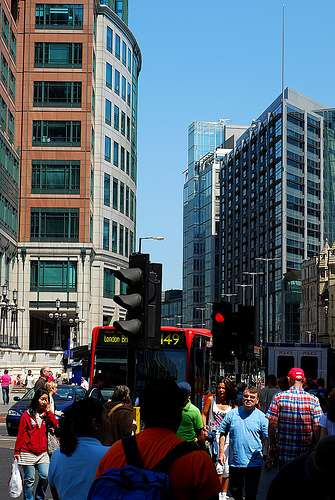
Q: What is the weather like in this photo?
A: It is clear.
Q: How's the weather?
A: It is clear.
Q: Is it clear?
A: Yes, it is clear.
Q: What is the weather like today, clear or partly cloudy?
A: It is clear.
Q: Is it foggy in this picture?
A: No, it is clear.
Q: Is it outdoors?
A: Yes, it is outdoors.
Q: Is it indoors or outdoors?
A: It is outdoors.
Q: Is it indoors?
A: No, it is outdoors.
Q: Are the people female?
A: No, they are both male and female.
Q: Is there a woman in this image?
A: Yes, there is a woman.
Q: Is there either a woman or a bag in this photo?
A: Yes, there is a woman.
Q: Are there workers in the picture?
A: No, there are no workers.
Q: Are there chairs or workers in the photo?
A: No, there are no workers or chairs.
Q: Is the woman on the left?
A: Yes, the woman is on the left of the image.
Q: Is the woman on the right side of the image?
A: No, the woman is on the left of the image.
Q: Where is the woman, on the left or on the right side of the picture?
A: The woman is on the left of the image.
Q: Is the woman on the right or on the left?
A: The woman is on the left of the image.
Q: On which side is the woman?
A: The woman is on the left of the image.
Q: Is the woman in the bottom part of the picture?
A: Yes, the woman is in the bottom of the image.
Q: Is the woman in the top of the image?
A: No, the woman is in the bottom of the image.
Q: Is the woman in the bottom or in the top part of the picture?
A: The woman is in the bottom of the image.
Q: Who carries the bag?
A: The woman carries the bag.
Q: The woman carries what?
A: The woman carries a bag.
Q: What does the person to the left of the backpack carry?
A: The woman carries a bag.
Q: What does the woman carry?
A: The woman carries a bag.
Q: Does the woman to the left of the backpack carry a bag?
A: Yes, the woman carries a bag.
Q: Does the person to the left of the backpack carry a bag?
A: Yes, the woman carries a bag.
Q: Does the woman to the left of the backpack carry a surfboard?
A: No, the woman carries a bag.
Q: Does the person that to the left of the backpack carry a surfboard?
A: No, the woman carries a bag.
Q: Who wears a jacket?
A: The woman wears a jacket.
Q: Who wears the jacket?
A: The woman wears a jacket.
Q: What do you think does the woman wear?
A: The woman wears a jacket.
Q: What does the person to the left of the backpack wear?
A: The woman wears a jacket.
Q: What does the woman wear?
A: The woman wears a jacket.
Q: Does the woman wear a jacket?
A: Yes, the woman wears a jacket.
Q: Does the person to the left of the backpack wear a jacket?
A: Yes, the woman wears a jacket.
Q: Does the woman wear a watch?
A: No, the woman wears a jacket.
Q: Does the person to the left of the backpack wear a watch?
A: No, the woman wears a jacket.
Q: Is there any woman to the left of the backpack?
A: Yes, there is a woman to the left of the backpack.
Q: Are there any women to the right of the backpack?
A: No, the woman is to the left of the backpack.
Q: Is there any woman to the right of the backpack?
A: No, the woman is to the left of the backpack.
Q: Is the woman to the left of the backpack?
A: Yes, the woman is to the left of the backpack.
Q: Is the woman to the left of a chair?
A: No, the woman is to the left of the backpack.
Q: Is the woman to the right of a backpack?
A: No, the woman is to the left of a backpack.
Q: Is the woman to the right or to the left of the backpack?
A: The woman is to the left of the backpack.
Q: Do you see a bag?
A: Yes, there is a bag.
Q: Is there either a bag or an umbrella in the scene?
A: Yes, there is a bag.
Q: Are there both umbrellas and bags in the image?
A: No, there is a bag but no umbrellas.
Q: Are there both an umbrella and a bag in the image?
A: No, there is a bag but no umbrellas.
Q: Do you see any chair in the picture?
A: No, there are no chairs.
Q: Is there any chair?
A: No, there are no chairs.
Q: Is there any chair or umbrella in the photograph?
A: No, there are no chairs or umbrellas.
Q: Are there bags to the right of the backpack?
A: No, the bag is to the left of the backpack.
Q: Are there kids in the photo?
A: No, there are no kids.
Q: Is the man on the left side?
A: Yes, the man is on the left of the image.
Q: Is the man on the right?
A: No, the man is on the left of the image.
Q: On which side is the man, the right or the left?
A: The man is on the left of the image.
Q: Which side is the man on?
A: The man is on the left of the image.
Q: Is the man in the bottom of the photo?
A: Yes, the man is in the bottom of the image.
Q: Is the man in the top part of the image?
A: No, the man is in the bottom of the image.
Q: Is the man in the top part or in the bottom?
A: The man is in the bottom of the image.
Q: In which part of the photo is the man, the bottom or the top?
A: The man is in the bottom of the image.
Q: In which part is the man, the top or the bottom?
A: The man is in the bottom of the image.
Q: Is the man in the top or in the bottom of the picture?
A: The man is in the bottom of the image.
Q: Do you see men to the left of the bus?
A: Yes, there is a man to the left of the bus.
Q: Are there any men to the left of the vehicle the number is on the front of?
A: Yes, there is a man to the left of the bus.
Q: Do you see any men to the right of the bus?
A: No, the man is to the left of the bus.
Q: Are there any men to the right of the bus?
A: No, the man is to the left of the bus.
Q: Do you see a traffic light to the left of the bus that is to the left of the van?
A: No, there is a man to the left of the bus.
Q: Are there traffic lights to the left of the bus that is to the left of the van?
A: No, there is a man to the left of the bus.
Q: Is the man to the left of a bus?
A: Yes, the man is to the left of a bus.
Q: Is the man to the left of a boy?
A: No, the man is to the left of a bus.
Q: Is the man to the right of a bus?
A: No, the man is to the left of a bus.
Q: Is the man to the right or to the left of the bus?
A: The man is to the left of the bus.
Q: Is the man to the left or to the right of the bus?
A: The man is to the left of the bus.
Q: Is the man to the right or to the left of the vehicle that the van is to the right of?
A: The man is to the left of the bus.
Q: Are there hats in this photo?
A: Yes, there is a hat.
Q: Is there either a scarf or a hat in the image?
A: Yes, there is a hat.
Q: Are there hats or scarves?
A: Yes, there is a hat.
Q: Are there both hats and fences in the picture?
A: No, there is a hat but no fences.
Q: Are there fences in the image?
A: No, there are no fences.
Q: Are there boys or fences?
A: No, there are no fences or boys.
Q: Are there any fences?
A: No, there are no fences.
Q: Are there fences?
A: No, there are no fences.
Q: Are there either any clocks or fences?
A: No, there are no fences or clocks.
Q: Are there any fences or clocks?
A: No, there are no fences or clocks.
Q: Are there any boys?
A: No, there are no boys.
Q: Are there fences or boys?
A: No, there are no boys or fences.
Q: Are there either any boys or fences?
A: No, there are no boys or fences.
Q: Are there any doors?
A: Yes, there is a door.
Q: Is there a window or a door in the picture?
A: Yes, there is a door.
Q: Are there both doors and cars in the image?
A: Yes, there are both a door and a car.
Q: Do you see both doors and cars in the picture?
A: Yes, there are both a door and a car.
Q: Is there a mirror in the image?
A: No, there are no mirrors.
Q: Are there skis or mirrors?
A: No, there are no mirrors or skis.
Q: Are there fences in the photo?
A: No, there are no fences.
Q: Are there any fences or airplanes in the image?
A: No, there are no fences or airplanes.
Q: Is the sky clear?
A: Yes, the sky is clear.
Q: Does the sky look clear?
A: Yes, the sky is clear.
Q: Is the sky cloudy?
A: No, the sky is clear.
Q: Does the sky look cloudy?
A: No, the sky is clear.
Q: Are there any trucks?
A: No, there are no trucks.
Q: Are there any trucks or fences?
A: No, there are no trucks or fences.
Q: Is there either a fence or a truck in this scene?
A: No, there are no trucks or fences.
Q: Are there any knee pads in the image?
A: No, there are no knee pads.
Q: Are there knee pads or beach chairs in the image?
A: No, there are no knee pads or beach chairs.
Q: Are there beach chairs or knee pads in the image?
A: No, there are no knee pads or beach chairs.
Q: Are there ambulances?
A: No, there are no ambulances.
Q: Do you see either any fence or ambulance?
A: No, there are no ambulances or fences.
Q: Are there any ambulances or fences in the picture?
A: No, there are no ambulances or fences.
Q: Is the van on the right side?
A: Yes, the van is on the right of the image.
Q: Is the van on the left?
A: No, the van is on the right of the image.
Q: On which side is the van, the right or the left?
A: The van is on the right of the image.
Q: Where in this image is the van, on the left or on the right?
A: The van is on the right of the image.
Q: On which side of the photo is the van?
A: The van is on the right of the image.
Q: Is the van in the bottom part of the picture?
A: Yes, the van is in the bottom of the image.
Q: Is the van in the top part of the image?
A: No, the van is in the bottom of the image.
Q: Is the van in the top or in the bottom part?
A: The van is in the bottom of the image.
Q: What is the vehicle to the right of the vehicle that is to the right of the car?
A: The vehicle is a van.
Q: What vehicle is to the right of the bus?
A: The vehicle is a van.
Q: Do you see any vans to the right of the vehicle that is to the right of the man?
A: Yes, there is a van to the right of the bus.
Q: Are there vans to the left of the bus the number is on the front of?
A: No, the van is to the right of the bus.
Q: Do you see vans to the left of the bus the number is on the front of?
A: No, the van is to the right of the bus.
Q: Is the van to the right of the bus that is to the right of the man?
A: Yes, the van is to the right of the bus.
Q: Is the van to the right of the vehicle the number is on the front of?
A: Yes, the van is to the right of the bus.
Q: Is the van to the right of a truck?
A: No, the van is to the right of the bus.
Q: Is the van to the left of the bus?
A: No, the van is to the right of the bus.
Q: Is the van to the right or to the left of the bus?
A: The van is to the right of the bus.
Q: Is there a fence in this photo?
A: No, there are no fences.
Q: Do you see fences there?
A: No, there are no fences.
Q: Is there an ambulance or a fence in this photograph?
A: No, there are no fences or ambulances.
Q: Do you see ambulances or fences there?
A: No, there are no fences or ambulances.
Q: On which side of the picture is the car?
A: The car is on the left of the image.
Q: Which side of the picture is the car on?
A: The car is on the left of the image.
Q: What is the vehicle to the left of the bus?
A: The vehicle is a car.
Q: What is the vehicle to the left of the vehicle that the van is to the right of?
A: The vehicle is a car.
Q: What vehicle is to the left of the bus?
A: The vehicle is a car.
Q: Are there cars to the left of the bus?
A: Yes, there is a car to the left of the bus.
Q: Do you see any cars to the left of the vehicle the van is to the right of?
A: Yes, there is a car to the left of the bus.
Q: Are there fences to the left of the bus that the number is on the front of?
A: No, there is a car to the left of the bus.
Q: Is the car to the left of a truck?
A: No, the car is to the left of the bus.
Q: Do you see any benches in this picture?
A: No, there are no benches.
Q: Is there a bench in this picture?
A: No, there are no benches.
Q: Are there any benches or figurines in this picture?
A: No, there are no benches or figurines.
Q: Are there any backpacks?
A: Yes, there is a backpack.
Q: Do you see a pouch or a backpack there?
A: Yes, there is a backpack.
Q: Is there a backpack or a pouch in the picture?
A: Yes, there is a backpack.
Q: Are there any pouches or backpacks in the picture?
A: Yes, there is a backpack.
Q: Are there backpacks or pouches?
A: Yes, there is a backpack.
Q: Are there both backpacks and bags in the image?
A: Yes, there are both a backpack and a bag.